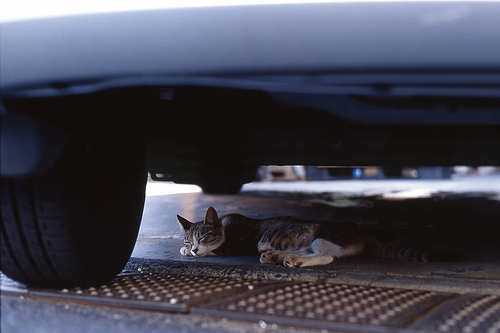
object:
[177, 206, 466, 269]
cat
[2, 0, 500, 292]
car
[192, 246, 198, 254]
nose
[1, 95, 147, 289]
tire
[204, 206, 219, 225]
ear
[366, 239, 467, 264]
tail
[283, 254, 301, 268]
feet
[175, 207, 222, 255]
head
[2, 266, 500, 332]
steel grate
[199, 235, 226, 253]
beard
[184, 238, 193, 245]
eyes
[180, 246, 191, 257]
paw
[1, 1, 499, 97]
bumper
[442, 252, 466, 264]
tip